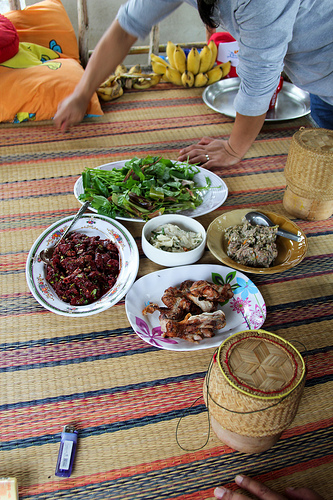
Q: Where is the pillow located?
A: Behind food.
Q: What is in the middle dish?
A: Dip.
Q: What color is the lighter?
A: Blue.